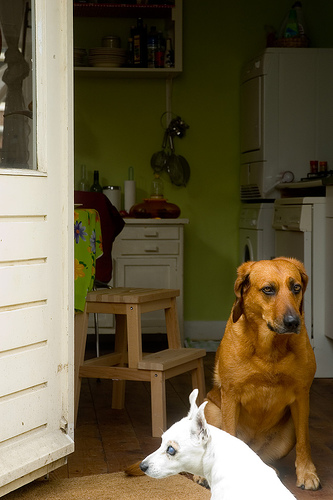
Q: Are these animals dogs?
A: Yes, all the animals are dogs.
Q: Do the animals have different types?
A: No, all the animals are dogs.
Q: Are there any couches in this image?
A: No, there are no couches.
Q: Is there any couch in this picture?
A: No, there are no couches.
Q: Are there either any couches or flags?
A: No, there are no couches or flags.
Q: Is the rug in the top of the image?
A: No, the rug is in the bottom of the image.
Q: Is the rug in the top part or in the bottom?
A: The rug is in the bottom of the image.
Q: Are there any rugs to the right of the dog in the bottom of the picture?
A: No, the rug is to the left of the dog.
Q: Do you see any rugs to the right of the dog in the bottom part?
A: No, the rug is to the left of the dog.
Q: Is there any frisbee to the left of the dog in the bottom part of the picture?
A: No, there is a rug to the left of the dog.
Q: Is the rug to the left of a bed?
A: No, the rug is to the left of the dog.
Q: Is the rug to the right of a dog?
A: No, the rug is to the left of a dog.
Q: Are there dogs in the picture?
A: Yes, there is a dog.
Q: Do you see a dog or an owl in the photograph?
A: Yes, there is a dog.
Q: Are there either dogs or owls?
A: Yes, there is a dog.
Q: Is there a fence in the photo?
A: No, there are no fences.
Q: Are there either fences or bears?
A: No, there are no fences or bears.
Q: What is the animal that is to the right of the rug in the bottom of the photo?
A: The animal is a dog.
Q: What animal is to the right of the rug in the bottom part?
A: The animal is a dog.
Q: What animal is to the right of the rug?
A: The animal is a dog.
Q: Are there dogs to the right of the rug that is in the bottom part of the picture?
A: Yes, there is a dog to the right of the rug.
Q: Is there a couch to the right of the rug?
A: No, there is a dog to the right of the rug.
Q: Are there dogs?
A: Yes, there is a dog.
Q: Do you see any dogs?
A: Yes, there is a dog.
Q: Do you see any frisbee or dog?
A: Yes, there is a dog.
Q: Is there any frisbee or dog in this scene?
A: Yes, there is a dog.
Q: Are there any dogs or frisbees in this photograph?
A: Yes, there is a dog.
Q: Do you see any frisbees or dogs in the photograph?
A: Yes, there is a dog.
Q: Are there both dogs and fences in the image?
A: No, there is a dog but no fences.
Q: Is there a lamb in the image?
A: No, there are no lambs.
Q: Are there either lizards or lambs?
A: No, there are no lambs or lizards.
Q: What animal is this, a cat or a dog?
A: This is a dog.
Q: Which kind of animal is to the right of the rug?
A: The animal is a dog.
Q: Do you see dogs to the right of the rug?
A: Yes, there is a dog to the right of the rug.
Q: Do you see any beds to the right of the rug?
A: No, there is a dog to the right of the rug.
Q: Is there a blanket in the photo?
A: No, there are no blankets.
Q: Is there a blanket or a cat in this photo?
A: No, there are no blankets or cats.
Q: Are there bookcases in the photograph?
A: No, there are no bookcases.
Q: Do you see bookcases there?
A: No, there are no bookcases.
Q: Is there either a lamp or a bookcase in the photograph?
A: No, there are no bookcases or lamps.